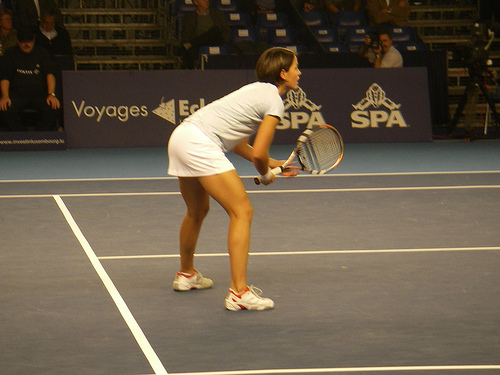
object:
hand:
[260, 165, 274, 185]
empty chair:
[198, 46, 230, 69]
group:
[225, 10, 294, 44]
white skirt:
[166, 121, 233, 178]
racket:
[252, 124, 346, 186]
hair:
[255, 46, 297, 85]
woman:
[166, 47, 303, 312]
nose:
[298, 69, 302, 75]